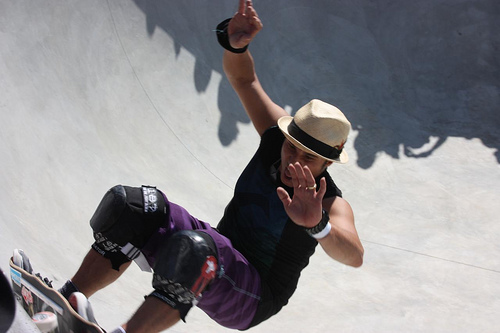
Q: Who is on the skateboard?
A: The man.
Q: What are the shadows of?
A: The spectators.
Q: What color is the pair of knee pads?
A: Black.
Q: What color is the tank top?
A: Black.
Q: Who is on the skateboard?
A: The man.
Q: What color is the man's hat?
A: Tan.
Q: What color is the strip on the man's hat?
A: Black.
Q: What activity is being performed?
A: Skateboarding.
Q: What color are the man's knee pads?
A: Black.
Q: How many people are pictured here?
A: One.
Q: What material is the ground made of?
A: Concrete.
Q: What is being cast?
A: Shadows.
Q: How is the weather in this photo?
A: Sunny.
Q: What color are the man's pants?
A: Purple.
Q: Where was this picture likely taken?
A: Skate park.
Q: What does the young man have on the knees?
A: The young man has black knee pads on the knees.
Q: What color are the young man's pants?
A: The young man's pants are purple in color.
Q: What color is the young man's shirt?
A: The young man's shirt is black.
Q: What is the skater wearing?
A: The skater is wearing purple shorts.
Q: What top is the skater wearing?
A: The skater is wearing a tank top.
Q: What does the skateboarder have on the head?
A: The skateboarder has a hat on the head.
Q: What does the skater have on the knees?
A: The skater has black pads on the knees.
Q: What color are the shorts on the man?
A: The shorts on the man are a purple color.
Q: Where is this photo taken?
A: Skate park.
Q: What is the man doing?
A: Skateboarding.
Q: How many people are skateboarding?
A: One.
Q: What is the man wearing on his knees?
A: Knee pads.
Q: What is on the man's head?
A: A hat.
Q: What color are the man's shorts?
A: Purple.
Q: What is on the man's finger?
A: A ring.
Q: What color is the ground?
A: Gray.